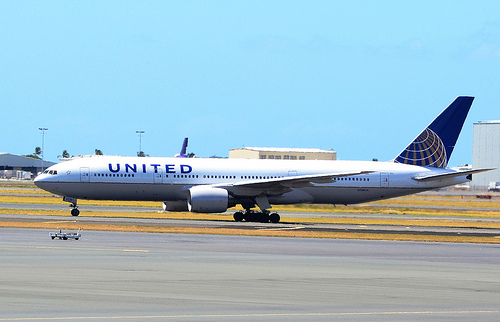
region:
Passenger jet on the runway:
[16, 95, 488, 243]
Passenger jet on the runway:
[30, 64, 499, 239]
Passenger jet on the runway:
[33, 84, 499, 220]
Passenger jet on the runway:
[26, 111, 498, 201]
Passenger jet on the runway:
[21, 80, 489, 257]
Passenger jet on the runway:
[33, 57, 489, 234]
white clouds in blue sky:
[202, 46, 234, 91]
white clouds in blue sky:
[385, 57, 418, 84]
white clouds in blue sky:
[224, 57, 264, 84]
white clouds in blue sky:
[248, 97, 283, 122]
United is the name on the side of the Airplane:
[103, 156, 205, 177]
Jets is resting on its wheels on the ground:
[228, 197, 297, 234]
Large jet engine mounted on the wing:
[181, 180, 241, 221]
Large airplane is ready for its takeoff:
[23, 79, 498, 274]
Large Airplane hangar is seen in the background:
[218, 131, 355, 188]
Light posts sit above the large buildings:
[29, 123, 154, 169]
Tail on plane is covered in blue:
[370, 81, 490, 202]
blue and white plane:
[21, 96, 478, 207]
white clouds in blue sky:
[45, 48, 76, 83]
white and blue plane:
[36, 89, 477, 226]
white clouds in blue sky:
[373, 26, 434, 64]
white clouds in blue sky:
[243, 93, 277, 140]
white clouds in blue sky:
[32, 39, 94, 79]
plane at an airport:
[28, 89, 496, 231]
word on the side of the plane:
[102, 157, 194, 179]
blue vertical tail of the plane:
[394, 90, 478, 171]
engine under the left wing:
[183, 185, 232, 213]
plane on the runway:
[33, 94, 494, 222]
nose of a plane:
[31, 176, 42, 186]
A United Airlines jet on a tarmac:
[31, 95, 488, 258]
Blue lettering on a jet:
[105, 162, 194, 176]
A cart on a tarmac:
[47, 217, 83, 239]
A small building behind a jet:
[3, 153, 55, 181]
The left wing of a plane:
[188, 167, 374, 207]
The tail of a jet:
[383, 95, 475, 172]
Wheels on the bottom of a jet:
[228, 203, 280, 226]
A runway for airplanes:
[3, 212, 495, 320]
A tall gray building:
[461, 117, 498, 185]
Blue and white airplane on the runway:
[36, 90, 489, 225]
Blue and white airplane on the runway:
[32, 95, 494, 214]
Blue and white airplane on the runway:
[31, 87, 491, 240]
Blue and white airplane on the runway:
[31, 90, 498, 250]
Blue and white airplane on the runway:
[19, 85, 494, 227]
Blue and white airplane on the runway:
[30, 90, 485, 242]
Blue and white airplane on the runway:
[19, 91, 495, 222]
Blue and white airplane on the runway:
[13, 84, 484, 224]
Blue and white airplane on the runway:
[18, 90, 496, 260]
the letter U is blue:
[108, 161, 121, 171]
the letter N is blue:
[124, 161, 136, 173]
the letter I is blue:
[142, 163, 147, 175]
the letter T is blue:
[151, 163, 161, 173]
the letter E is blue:
[163, 160, 175, 174]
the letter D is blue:
[179, 163, 191, 174]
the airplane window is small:
[93, 171, 98, 177]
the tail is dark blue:
[391, 96, 473, 169]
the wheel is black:
[69, 207, 79, 216]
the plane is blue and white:
[36, 94, 497, 221]